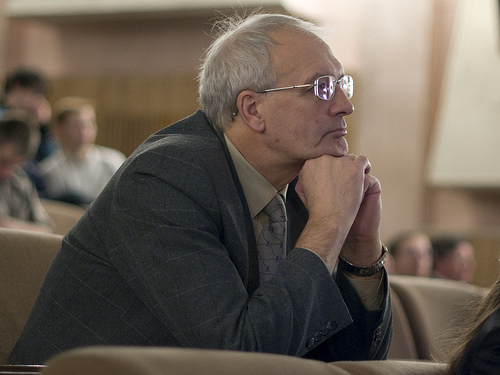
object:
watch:
[337, 243, 390, 276]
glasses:
[257, 75, 354, 100]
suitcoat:
[6, 107, 394, 365]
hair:
[197, 13, 322, 134]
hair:
[1, 118, 43, 160]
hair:
[55, 111, 71, 124]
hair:
[1, 66, 51, 94]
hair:
[437, 278, 499, 374]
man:
[430, 230, 479, 285]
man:
[389, 227, 434, 279]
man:
[0, 112, 53, 233]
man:
[34, 98, 129, 201]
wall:
[282, 1, 435, 253]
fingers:
[354, 153, 371, 173]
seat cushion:
[389, 274, 487, 361]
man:
[0, 11, 394, 366]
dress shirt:
[223, 135, 288, 287]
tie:
[256, 194, 288, 287]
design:
[256, 228, 286, 264]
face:
[263, 36, 355, 159]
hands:
[298, 152, 370, 218]